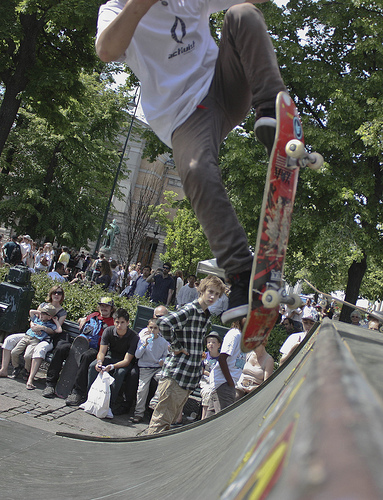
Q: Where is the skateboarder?
A: Park.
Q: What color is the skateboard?
A: Red.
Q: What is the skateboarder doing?
A: Tricks.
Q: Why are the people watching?
A: Skateboarder doing tricks.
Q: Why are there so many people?
A: Events.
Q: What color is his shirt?
A: White.